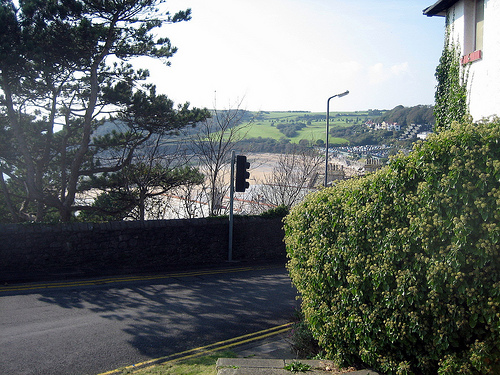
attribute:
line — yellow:
[88, 317, 297, 373]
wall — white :
[447, 2, 497, 123]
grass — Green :
[246, 121, 343, 146]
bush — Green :
[281, 119, 498, 372]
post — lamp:
[325, 87, 346, 187]